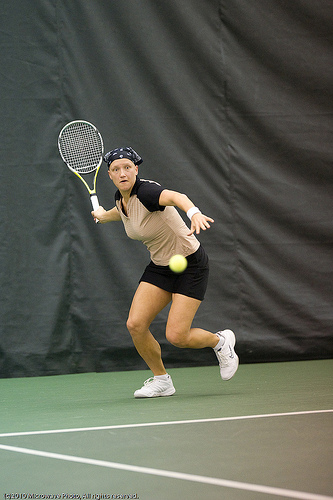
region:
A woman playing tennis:
[54, 115, 251, 401]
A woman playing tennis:
[55, 116, 247, 400]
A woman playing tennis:
[56, 119, 242, 400]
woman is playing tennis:
[47, 111, 246, 404]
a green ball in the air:
[159, 249, 193, 281]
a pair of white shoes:
[124, 327, 249, 402]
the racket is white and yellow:
[54, 115, 108, 225]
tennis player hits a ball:
[50, 113, 250, 404]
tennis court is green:
[2, 359, 331, 498]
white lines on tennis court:
[0, 402, 332, 498]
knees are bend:
[121, 309, 192, 352]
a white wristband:
[182, 201, 202, 226]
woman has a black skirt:
[89, 142, 245, 404]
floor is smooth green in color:
[60, 382, 96, 420]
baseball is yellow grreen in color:
[163, 245, 191, 289]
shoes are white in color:
[129, 370, 193, 396]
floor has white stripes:
[158, 411, 202, 433]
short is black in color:
[152, 256, 221, 297]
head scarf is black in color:
[103, 141, 137, 161]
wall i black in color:
[216, 60, 295, 172]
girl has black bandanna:
[101, 148, 147, 170]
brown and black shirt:
[101, 186, 173, 253]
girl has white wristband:
[185, 207, 200, 225]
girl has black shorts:
[148, 235, 208, 302]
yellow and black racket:
[67, 116, 100, 214]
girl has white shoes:
[207, 335, 242, 381]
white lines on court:
[0, 414, 283, 490]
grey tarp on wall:
[5, 24, 293, 380]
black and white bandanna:
[106, 144, 145, 171]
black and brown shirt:
[114, 180, 197, 269]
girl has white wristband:
[186, 204, 198, 220]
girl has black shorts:
[150, 258, 209, 287]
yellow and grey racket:
[55, 124, 98, 197]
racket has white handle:
[88, 190, 110, 236]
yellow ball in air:
[165, 245, 193, 291]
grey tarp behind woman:
[112, 9, 318, 236]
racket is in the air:
[56, 118, 103, 222]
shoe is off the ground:
[212, 324, 237, 377]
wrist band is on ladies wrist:
[186, 205, 199, 217]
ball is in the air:
[167, 252, 187, 273]